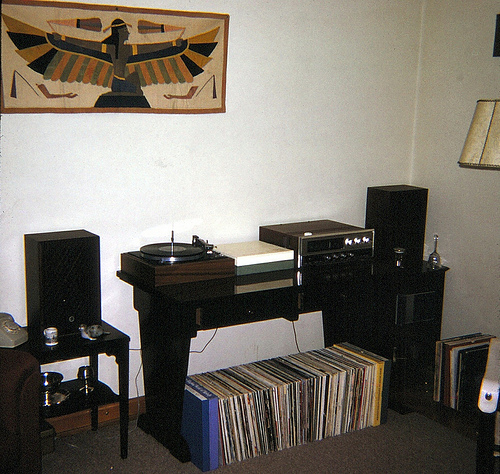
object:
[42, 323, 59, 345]
white cup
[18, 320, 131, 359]
table top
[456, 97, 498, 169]
lampshade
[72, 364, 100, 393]
items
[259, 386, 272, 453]
records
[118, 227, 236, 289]
turntable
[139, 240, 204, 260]
record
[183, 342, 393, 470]
album collection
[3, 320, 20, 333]
rotary dial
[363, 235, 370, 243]
dial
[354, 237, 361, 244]
dial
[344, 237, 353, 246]
dial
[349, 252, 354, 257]
dial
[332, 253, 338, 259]
dial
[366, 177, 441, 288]
speaker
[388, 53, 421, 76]
ground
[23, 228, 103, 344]
speaker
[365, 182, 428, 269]
speaker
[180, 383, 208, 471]
album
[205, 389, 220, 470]
album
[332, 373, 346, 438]
album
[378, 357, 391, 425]
album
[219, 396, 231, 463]
album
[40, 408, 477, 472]
floor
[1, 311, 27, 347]
phone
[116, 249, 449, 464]
desk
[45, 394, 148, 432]
baseboard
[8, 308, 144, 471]
table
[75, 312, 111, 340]
item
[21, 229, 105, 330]
item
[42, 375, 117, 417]
bottom shelf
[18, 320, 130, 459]
table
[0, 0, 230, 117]
frame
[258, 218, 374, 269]
stereo component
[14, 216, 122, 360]
speaker